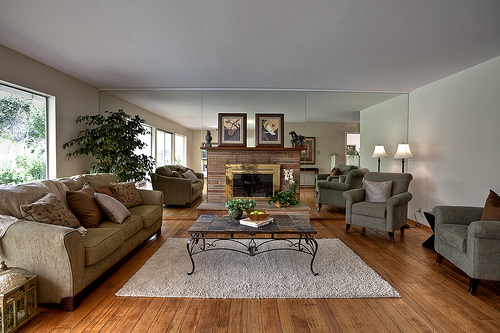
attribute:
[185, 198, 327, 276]
coffee table — big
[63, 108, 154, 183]
plant — large, leafy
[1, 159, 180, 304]
sofa — nice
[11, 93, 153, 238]
window — large, clear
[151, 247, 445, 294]
rug — white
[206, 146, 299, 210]
fireplace — brick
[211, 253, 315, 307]
carpet — white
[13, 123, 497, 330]
furniture — nice, comfortable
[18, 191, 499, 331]
floor — hardwood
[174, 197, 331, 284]
table — stone, tiled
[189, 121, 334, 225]
fire place — brick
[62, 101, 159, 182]
tree — green, leafy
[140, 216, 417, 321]
rug — cream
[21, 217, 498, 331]
floor — pretty, brown, wooden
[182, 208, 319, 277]
coffee table — metal, stone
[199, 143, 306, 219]
fireplace — modern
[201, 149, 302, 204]
fireplace — big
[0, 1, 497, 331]
room — furnished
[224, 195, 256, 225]
plant — green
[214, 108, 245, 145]
painting — framed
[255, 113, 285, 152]
painting — framed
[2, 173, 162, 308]
couch — tan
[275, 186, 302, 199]
leaves — green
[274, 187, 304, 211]
plant — potted